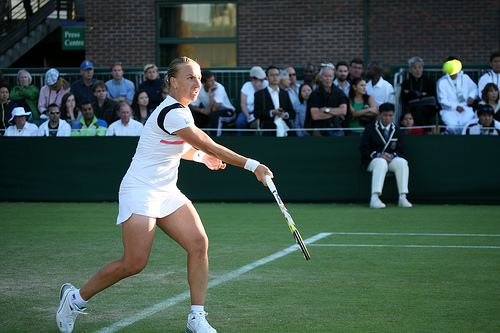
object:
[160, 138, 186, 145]
strip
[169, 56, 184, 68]
hair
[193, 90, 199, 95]
womans mouth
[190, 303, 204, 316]
socks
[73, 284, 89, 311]
socks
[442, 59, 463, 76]
ball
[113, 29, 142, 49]
air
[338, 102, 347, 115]
arms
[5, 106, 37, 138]
person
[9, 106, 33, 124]
hat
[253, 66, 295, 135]
person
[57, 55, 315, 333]
tennis match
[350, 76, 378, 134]
woman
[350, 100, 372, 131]
shirt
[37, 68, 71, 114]
person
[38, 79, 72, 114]
shirt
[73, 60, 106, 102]
man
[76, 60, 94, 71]
hat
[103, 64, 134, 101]
man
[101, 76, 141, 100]
shirt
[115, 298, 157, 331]
line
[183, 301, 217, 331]
shoes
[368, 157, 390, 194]
pants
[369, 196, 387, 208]
shoes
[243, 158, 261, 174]
band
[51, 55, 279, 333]
player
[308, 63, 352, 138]
man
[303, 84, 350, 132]
shirt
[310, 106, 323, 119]
arms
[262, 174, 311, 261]
racket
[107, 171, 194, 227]
skirt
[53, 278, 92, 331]
shoes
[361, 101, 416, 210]
man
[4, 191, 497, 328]
court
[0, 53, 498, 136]
spectators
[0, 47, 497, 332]
match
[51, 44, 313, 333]
tennis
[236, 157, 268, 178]
wristband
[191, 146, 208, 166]
wrist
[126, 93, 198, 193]
shirt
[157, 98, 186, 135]
stripe